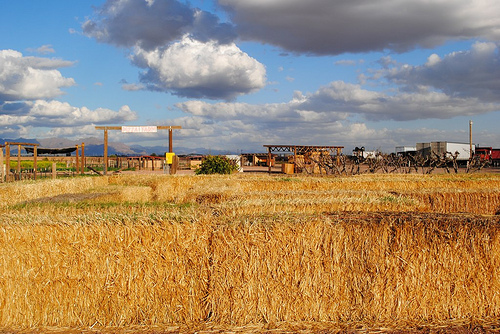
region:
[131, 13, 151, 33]
the cloud is gray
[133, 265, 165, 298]
the hay is yellow tan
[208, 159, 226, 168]
the bush is green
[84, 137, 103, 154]
the mountains are in the background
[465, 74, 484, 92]
the cloud has gray in it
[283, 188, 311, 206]
the hay is dead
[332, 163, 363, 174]
the fence posts are weathered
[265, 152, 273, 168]
the post is brown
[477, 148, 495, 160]
the truck is red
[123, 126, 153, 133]
the sign is on the post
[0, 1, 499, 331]
vibrant, & likely natural colour, ranchland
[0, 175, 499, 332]
multiple yellow orange, rusty beige, bales of hay, with green dispersed there & here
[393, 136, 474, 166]
i believe @ least two horse trailers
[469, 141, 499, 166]
the bright red cab of a bright red truck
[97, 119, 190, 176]
entryway to ranch, w/ ranch's name too far away to read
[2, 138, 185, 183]
typical low wooden ranch fence with some slightly higher gates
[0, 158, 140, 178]
green grass, scrub or possibly even vegetables on the ground behind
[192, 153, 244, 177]
a large green brush of a bush @ centre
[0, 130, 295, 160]
some long blue grey mountains in the back, some dark clouds mixed with the little fluffy clouds above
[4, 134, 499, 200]
not a single animal--or even person--visible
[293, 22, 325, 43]
the cloud is gray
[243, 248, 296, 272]
the hay is tan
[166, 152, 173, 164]
the sign is yellow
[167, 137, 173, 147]
the pole is brown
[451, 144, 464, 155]
the trailer is white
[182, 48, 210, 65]
the cloud is white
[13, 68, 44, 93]
the clouds are fluffy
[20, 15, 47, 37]
the sky is blue in color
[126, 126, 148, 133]
the sign is white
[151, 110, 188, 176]
This is a pole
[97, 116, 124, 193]
This is a pole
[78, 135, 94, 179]
This is a pole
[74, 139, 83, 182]
This is a pole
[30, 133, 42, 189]
This is a pole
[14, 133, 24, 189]
This is a pole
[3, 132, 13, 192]
This is a pole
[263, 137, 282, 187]
This is a pole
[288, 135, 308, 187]
This is a pole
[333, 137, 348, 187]
This is a pole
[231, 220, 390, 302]
dry fodder in the field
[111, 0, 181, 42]
dark clouds in the sky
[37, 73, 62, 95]
white clouds in the sky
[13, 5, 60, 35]
blue skies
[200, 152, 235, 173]
a tree in the field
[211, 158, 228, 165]
green leaves of a plant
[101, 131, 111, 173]
a wooden pole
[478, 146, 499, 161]
a red truck in the distant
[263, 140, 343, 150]
the top of a shade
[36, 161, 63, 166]
green plants in the field